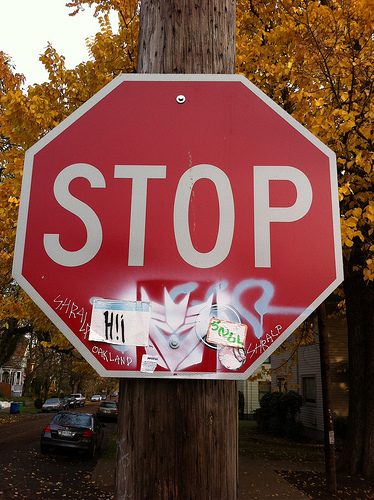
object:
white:
[78, 396, 82, 399]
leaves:
[351, 207, 363, 216]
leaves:
[353, 191, 365, 203]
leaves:
[358, 231, 364, 243]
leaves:
[354, 208, 364, 219]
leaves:
[346, 217, 358, 227]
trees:
[237, 0, 374, 500]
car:
[98, 400, 119, 421]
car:
[65, 398, 77, 409]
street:
[0, 393, 120, 498]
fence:
[0, 399, 14, 408]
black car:
[41, 414, 107, 458]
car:
[91, 394, 103, 402]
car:
[42, 396, 61, 412]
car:
[70, 393, 86, 408]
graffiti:
[90, 277, 308, 367]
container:
[10, 402, 20, 415]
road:
[0, 394, 120, 500]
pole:
[317, 303, 349, 500]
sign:
[12, 70, 342, 384]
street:
[2, 395, 107, 500]